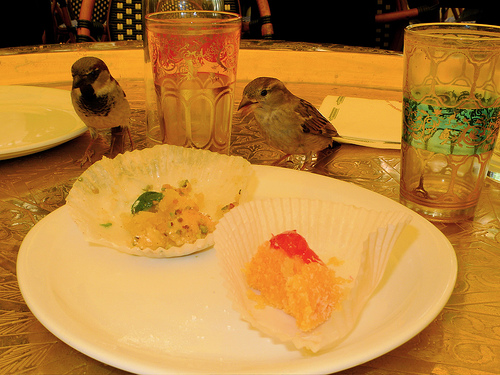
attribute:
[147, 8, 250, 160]
glass — small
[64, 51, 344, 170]
birds — small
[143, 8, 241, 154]
glass — with red and gold accents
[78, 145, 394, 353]
white plate — empty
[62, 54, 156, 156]
bird — small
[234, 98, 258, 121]
beak — open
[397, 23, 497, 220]
glass — large, drinking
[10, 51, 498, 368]
table top — gold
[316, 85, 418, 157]
napkin — white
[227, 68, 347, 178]
bird — open-beaked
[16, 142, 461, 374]
plate — white, round, empty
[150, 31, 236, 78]
design — red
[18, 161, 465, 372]
plate — white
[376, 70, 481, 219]
glass — small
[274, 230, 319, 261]
cherry — red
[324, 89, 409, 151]
napkin — white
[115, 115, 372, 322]
food — partially eaten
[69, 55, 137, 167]
bird — dark chested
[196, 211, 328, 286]
cherry — green 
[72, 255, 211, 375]
plate — white